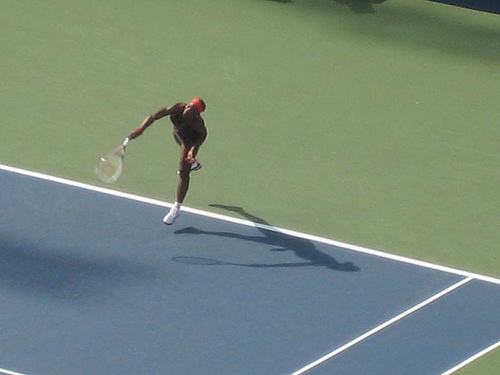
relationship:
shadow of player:
[171, 203, 362, 273] [128, 94, 209, 224]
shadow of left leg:
[171, 203, 362, 273] [176, 143, 200, 203]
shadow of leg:
[171, 203, 362, 273] [170, 223, 267, 243]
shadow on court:
[171, 203, 362, 273] [1, 249, 315, 341]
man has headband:
[127, 97, 207, 226] [188, 94, 203, 119]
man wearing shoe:
[127, 97, 207, 226] [161, 206, 180, 225]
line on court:
[371, 296, 427, 343] [148, 283, 225, 338]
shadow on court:
[169, 203, 360, 278] [1, 249, 315, 341]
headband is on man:
[190, 97, 205, 114] [127, 97, 207, 227]